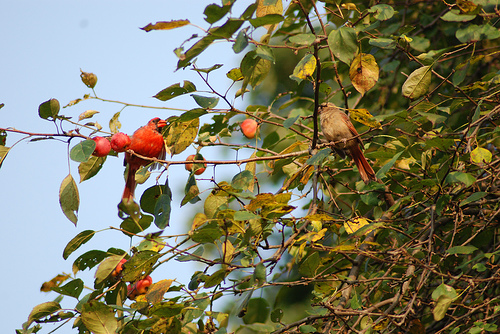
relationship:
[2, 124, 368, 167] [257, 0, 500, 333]
branch from tree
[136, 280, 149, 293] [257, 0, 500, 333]
berry in tree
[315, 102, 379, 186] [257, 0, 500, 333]
bird in tree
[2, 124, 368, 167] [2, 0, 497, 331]
branch has leaves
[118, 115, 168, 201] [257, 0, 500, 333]
bird in tree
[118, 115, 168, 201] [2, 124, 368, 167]
bird sitting on branch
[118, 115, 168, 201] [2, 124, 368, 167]
bird resting on branch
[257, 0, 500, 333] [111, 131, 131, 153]
tree with fruit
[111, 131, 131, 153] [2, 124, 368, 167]
fruit on branch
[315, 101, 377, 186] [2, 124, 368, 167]
bird are sitting on branch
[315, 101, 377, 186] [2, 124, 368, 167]
bird perched on a branch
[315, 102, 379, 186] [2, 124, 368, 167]
bird on a branch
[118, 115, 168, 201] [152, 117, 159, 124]
bird has eyes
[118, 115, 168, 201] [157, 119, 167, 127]
bird has beak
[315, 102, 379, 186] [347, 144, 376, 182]
bird has a tail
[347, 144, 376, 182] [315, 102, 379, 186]
tail of bird